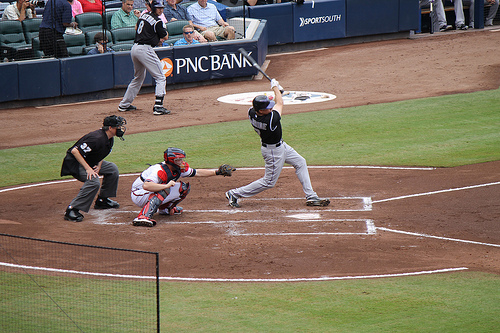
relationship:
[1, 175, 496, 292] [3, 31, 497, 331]
lines on field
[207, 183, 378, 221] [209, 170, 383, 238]
foot inside lines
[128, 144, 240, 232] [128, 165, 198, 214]
catcher wearing white uniform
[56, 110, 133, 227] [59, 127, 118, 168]
umpire wearing black shirt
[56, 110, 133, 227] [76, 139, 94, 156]
umpire shirt has 37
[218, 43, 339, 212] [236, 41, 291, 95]
player swinging bat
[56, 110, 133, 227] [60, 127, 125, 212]
umpire in dark clothing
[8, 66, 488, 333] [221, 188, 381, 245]
field has home plate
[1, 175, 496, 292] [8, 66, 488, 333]
circle at baseball field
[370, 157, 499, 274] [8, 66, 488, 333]
line on baseball field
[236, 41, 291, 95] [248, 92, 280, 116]
bat above head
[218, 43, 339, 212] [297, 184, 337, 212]
athlete with a twisted foot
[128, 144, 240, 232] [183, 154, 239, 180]
catcher arm extended in front of him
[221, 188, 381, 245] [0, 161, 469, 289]
rectangles within an oval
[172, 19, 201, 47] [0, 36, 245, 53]
fan in first row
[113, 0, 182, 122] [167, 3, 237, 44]
player standing near fans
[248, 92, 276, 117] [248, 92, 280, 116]
helmet over head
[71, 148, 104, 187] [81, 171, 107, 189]
hand resting on knee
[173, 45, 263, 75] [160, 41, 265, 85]
pnc bank written on wall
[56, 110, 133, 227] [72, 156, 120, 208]
man wearing gray pants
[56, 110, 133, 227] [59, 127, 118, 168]
man wearing black shirt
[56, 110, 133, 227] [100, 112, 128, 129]
man wearing black hat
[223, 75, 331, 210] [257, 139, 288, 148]
batter wearing black belt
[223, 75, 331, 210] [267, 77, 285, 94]
batter wearing white glove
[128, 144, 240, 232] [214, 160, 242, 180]
catcher has black mitt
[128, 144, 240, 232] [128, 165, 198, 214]
man wearing white uniform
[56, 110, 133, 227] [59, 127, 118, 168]
umpire has black shirt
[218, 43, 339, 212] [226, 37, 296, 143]
batter in position to strik to strike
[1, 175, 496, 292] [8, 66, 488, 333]
turf on ground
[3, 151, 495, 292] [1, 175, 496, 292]
turf has white lines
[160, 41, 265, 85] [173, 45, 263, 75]
sign of pnc bank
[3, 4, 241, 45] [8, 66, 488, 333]
audience watching game